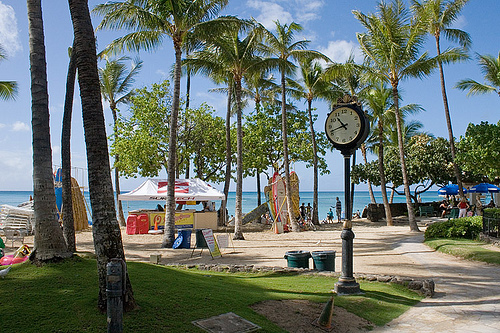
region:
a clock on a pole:
[320, 94, 375, 289]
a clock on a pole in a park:
[252, 89, 492, 324]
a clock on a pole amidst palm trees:
[155, 29, 490, 298]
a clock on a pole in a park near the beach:
[297, 85, 392, 307]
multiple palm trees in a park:
[19, 5, 474, 242]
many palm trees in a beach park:
[82, 0, 494, 235]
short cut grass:
[10, 266, 439, 328]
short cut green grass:
[9, 269, 409, 325]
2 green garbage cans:
[275, 240, 336, 275]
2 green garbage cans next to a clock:
[277, 103, 374, 294]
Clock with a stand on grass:
[314, 78, 381, 303]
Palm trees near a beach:
[212, 1, 324, 238]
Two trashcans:
[272, 237, 339, 273]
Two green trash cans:
[281, 242, 337, 275]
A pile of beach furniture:
[5, 196, 35, 238]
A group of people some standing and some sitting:
[431, 192, 486, 222]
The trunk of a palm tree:
[67, 57, 132, 248]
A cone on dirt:
[304, 278, 337, 331]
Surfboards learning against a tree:
[266, 168, 308, 230]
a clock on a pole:
[323, 90, 374, 294]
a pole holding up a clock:
[322, 100, 372, 285]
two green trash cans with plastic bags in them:
[280, 248, 340, 270]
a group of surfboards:
[263, 168, 306, 228]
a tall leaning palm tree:
[412, 2, 476, 202]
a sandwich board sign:
[190, 229, 225, 259]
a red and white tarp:
[119, 179, 227, 205]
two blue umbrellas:
[438, 181, 498, 198]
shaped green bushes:
[425, 214, 486, 243]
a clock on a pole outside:
[325, 95, 371, 296]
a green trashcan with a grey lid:
[310, 249, 337, 269]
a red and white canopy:
[118, 178, 225, 200]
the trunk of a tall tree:
[68, 0, 135, 312]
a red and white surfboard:
[273, 173, 290, 233]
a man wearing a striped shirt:
[334, 195, 343, 223]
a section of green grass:
[2, 258, 424, 331]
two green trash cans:
[285, 249, 335, 269]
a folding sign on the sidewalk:
[194, 228, 223, 263]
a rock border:
[164, 260, 434, 295]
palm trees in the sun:
[131, 3, 461, 90]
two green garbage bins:
[285, 248, 338, 274]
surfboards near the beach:
[266, 171, 301, 226]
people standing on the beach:
[301, 197, 341, 222]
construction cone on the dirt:
[317, 295, 337, 328]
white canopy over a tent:
[118, 176, 222, 202]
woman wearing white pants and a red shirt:
[457, 196, 468, 216]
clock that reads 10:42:
[322, 96, 371, 151]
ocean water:
[303, 190, 373, 196]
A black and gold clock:
[290, 90, 395, 312]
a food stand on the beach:
[96, 160, 236, 268]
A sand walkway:
[340, 214, 445, 307]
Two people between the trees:
[325, 177, 350, 224]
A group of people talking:
[427, 178, 490, 228]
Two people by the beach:
[345, 204, 370, 230]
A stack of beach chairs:
[0, 195, 39, 268]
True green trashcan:
[285, 238, 337, 276]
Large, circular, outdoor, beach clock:
[320, 95, 372, 300]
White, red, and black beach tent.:
[115, 173, 232, 235]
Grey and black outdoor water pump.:
[93, 248, 138, 331]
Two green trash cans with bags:
[280, 246, 341, 271]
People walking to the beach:
[433, 193, 492, 228]